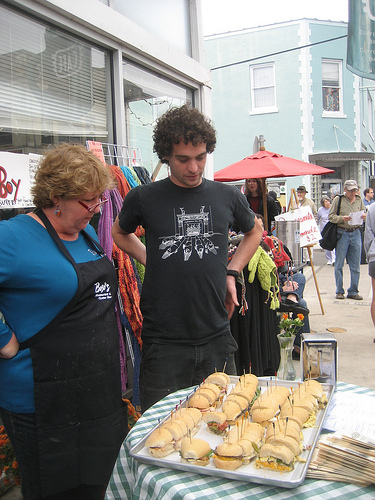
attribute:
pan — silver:
[130, 373, 335, 491]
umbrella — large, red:
[211, 143, 334, 188]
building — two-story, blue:
[219, 38, 340, 134]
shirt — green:
[326, 193, 364, 231]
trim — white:
[298, 28, 315, 153]